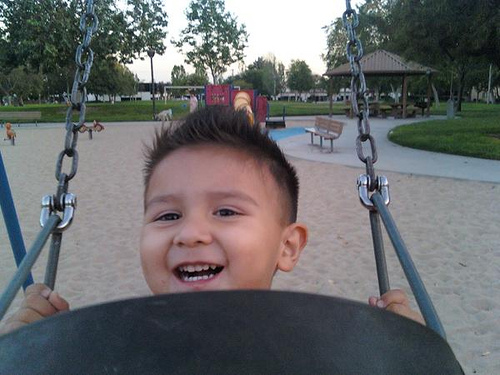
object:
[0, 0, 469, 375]
swing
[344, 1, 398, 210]
chain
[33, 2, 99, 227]
chain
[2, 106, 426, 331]
boy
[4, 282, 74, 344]
hand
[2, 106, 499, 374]
playground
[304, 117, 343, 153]
bench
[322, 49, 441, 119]
shelter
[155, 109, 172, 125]
dog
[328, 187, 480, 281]
sand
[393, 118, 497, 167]
grassy area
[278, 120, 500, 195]
sidewalk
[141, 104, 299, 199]
hair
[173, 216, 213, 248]
nose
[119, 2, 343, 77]
sky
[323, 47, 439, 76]
roof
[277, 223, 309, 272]
ear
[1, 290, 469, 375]
tire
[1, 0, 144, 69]
trees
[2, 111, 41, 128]
bench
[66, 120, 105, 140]
rocking horse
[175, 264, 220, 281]
teeth